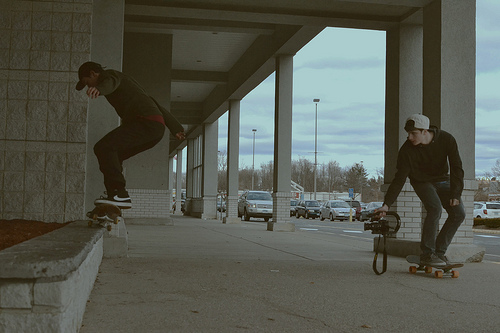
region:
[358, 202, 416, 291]
camera used for filming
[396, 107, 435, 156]
Man wearing white hat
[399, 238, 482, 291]
skateboard on the sidewalk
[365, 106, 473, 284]
boy wearing sweatshirt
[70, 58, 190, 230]
skater performing trick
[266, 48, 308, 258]
Columns holding up building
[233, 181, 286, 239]
vehicle with lights on in the background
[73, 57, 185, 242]
a man rides on a skateboard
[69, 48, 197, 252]
a kid does skateboard tricks outside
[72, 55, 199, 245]
a man skateboarding on a small ledge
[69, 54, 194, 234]
a guy grinds on a curbside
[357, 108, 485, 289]
a skater carries a camera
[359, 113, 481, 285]
a guy with a skateboard pointing his camera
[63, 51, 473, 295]
a skateboarder films another skaters tricks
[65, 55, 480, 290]
two skaters skate under a grocery store cover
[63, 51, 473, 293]
teenagers skate in a parking lot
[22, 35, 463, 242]
these are two men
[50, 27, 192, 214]
the man is a skater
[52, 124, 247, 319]
the skater is grinding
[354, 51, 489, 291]
the man is filming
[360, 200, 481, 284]
the man with the camera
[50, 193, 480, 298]
they are both riding skateboards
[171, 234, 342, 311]
the ground is light gray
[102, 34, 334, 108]
this is a covered area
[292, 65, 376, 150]
the sky is overcast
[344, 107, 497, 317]
Boy skating on board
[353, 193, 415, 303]
Boy holding a camera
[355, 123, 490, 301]
boy wearing a sweatshirt with a hood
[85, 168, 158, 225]
skater wearing nike shoes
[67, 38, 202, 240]
skater doing a trick on the ledge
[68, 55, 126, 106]
Skater wearing a hat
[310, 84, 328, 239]
Tall light posts in the parking lot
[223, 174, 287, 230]
vehicle parked near the shopping center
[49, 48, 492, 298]
skaters filming an event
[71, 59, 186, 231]
Shirt boy on skateboard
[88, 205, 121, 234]
Small long wood skateboard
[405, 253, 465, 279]
Small wood long skateboard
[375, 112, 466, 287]
Boy with white hat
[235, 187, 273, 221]
Small parked metal silver car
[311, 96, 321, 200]
Large tall metal pole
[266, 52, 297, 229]
Large tall concrete column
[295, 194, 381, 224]
Cars in parking lot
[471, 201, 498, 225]
Small white parked car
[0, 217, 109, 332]
Long grey concrete ledge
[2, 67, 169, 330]
a skateboarder grinding on a concrete ledge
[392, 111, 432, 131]
a male wearing a white baseball cap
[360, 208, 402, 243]
a male holding a video camera